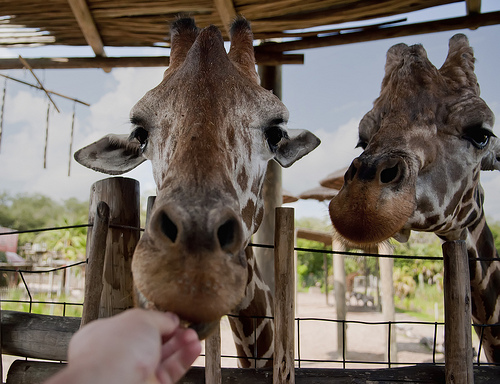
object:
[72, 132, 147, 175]
ear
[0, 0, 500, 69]
roof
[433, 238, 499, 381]
wall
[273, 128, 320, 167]
ear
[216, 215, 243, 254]
nostril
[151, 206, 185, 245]
nostril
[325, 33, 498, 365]
giraffes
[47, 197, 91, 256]
trees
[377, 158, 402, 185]
nostrils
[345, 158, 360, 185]
nostrils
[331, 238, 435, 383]
fence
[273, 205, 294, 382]
pole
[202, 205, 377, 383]
fence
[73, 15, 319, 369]
giraffe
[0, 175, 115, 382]
fence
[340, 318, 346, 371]
wire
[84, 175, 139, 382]
pole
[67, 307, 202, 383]
hand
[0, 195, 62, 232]
tree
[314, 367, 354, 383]
dirt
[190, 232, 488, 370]
path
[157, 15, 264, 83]
horns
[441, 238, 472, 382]
posts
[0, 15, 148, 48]
structure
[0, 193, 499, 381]
area